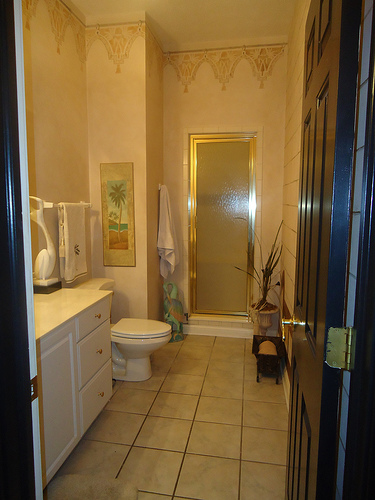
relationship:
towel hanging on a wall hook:
[61, 201, 91, 283] [84, 201, 93, 215]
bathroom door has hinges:
[300, 15, 352, 348] [326, 324, 358, 372]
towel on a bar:
[61, 201, 91, 283] [48, 200, 61, 209]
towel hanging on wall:
[61, 201, 91, 283] [168, 66, 266, 98]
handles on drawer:
[95, 310, 104, 324] [83, 306, 115, 331]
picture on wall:
[100, 160, 138, 271] [168, 66, 266, 98]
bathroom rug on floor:
[50, 475, 140, 500] [169, 393, 252, 450]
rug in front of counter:
[59, 479, 97, 500] [37, 303, 68, 328]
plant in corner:
[244, 233, 281, 302] [273, 204, 287, 226]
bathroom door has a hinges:
[300, 15, 352, 348] [326, 324, 358, 372]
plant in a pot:
[244, 233, 281, 302] [248, 249, 280, 287]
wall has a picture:
[168, 66, 266, 98] [100, 160, 138, 271]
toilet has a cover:
[115, 312, 170, 364] [124, 314, 160, 336]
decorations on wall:
[47, 8, 147, 78] [168, 66, 266, 98]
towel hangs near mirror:
[61, 201, 91, 283] [203, 151, 237, 262]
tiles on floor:
[173, 357, 239, 398] [169, 393, 252, 450]